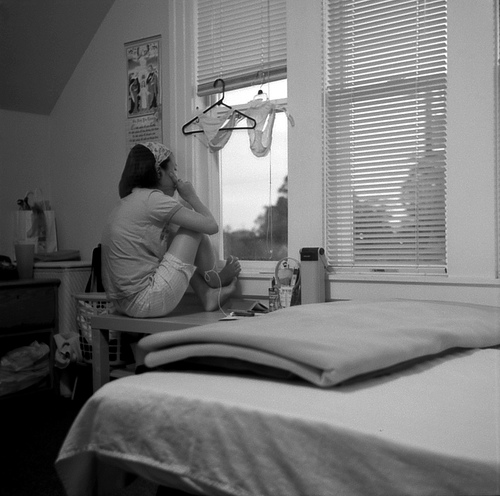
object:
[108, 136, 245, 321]
girl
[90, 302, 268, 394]
table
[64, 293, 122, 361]
laundry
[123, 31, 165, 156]
calendar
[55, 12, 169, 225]
wall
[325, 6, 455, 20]
blinds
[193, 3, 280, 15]
blinds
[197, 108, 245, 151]
panties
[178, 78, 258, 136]
hanger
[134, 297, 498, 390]
blanket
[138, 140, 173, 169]
bandana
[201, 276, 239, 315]
feet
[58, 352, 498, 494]
sheet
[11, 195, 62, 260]
bag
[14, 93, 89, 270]
corner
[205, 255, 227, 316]
cord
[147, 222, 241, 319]
legs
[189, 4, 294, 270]
window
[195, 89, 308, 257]
out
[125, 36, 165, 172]
poster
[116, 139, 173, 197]
hair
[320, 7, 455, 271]
window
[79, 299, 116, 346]
clothes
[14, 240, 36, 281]
cup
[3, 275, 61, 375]
desk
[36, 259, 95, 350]
laundry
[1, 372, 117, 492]
floor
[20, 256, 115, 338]
hamper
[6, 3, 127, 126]
roof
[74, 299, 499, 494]
bed